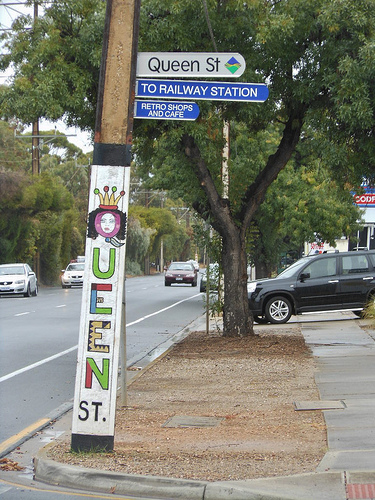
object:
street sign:
[134, 77, 270, 104]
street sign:
[132, 99, 201, 121]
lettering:
[140, 83, 148, 93]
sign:
[136, 52, 247, 77]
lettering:
[147, 56, 161, 74]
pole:
[65, 0, 143, 466]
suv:
[248, 250, 374, 324]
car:
[163, 261, 199, 287]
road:
[0, 270, 219, 443]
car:
[60, 259, 84, 288]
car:
[1, 262, 39, 300]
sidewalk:
[296, 316, 374, 499]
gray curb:
[32, 460, 290, 499]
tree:
[1, 2, 374, 338]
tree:
[251, 138, 366, 279]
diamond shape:
[224, 56, 242, 75]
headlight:
[61, 275, 69, 280]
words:
[78, 401, 89, 421]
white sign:
[70, 141, 133, 456]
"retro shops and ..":
[141, 102, 193, 117]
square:
[293, 398, 346, 412]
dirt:
[48, 327, 327, 488]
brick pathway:
[346, 483, 374, 499]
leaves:
[1, 455, 17, 470]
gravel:
[197, 337, 212, 348]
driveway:
[203, 307, 374, 330]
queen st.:
[79, 212, 121, 425]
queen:
[86, 184, 128, 248]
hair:
[86, 208, 128, 239]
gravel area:
[47, 330, 326, 479]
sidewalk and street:
[0, 273, 374, 499]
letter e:
[87, 320, 112, 352]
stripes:
[86, 321, 94, 352]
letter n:
[84, 357, 110, 390]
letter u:
[91, 247, 116, 280]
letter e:
[89, 282, 113, 315]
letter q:
[94, 210, 125, 248]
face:
[100, 212, 116, 234]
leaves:
[294, 22, 321, 59]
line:
[1, 293, 202, 392]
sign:
[349, 184, 374, 209]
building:
[304, 177, 373, 253]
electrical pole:
[30, 1, 41, 179]